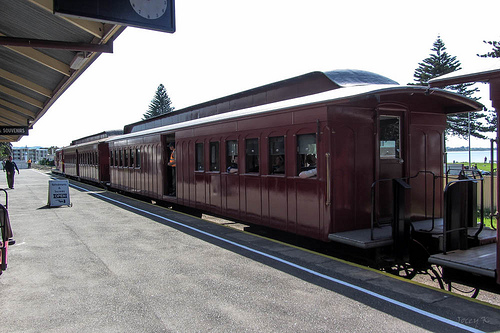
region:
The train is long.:
[51, 68, 498, 301]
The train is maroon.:
[51, 58, 498, 313]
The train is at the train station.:
[41, 65, 499, 315]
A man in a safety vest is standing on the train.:
[118, 103, 398, 259]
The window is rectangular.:
[373, 109, 405, 164]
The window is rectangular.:
[289, 130, 325, 190]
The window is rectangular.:
[263, 129, 290, 180]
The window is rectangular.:
[238, 130, 263, 180]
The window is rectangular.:
[220, 135, 243, 180]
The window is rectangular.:
[205, 135, 225, 175]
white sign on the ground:
[48, 173, 71, 207]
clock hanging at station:
[126, 0, 166, 27]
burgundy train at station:
[51, 77, 438, 198]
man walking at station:
[4, 153, 23, 189]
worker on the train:
[166, 142, 176, 184]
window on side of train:
[297, 129, 317, 180]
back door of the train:
[381, 114, 406, 213]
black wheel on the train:
[383, 249, 415, 284]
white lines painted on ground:
[72, 192, 499, 330]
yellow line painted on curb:
[427, 278, 498, 312]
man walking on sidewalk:
[2, 155, 15, 189]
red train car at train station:
[167, 64, 465, 204]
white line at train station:
[186, 220, 261, 260]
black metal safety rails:
[369, 174, 414, 242]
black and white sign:
[44, 175, 74, 210]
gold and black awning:
[2, 68, 72, 123]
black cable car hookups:
[412, 256, 479, 299]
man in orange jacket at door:
[158, 133, 180, 195]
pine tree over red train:
[141, 83, 172, 120]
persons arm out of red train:
[291, 134, 320, 181]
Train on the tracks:
[170, 68, 470, 315]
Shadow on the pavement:
[284, 233, 369, 328]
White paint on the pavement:
[288, 243, 344, 298]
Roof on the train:
[252, 47, 429, 105]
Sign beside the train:
[33, 163, 98, 215]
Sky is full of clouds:
[225, 19, 285, 66]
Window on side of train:
[253, 140, 297, 191]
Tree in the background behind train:
[405, 9, 487, 135]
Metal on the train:
[362, 180, 432, 249]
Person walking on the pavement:
[2, 153, 27, 193]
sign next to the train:
[44, 175, 72, 214]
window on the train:
[370, 110, 404, 165]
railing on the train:
[363, 175, 394, 240]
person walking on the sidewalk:
[3, 145, 21, 189]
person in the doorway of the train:
[157, 136, 178, 199]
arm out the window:
[295, 165, 315, 181]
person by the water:
[472, 155, 495, 169]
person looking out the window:
[225, 153, 239, 176]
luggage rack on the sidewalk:
[2, 189, 12, 274]